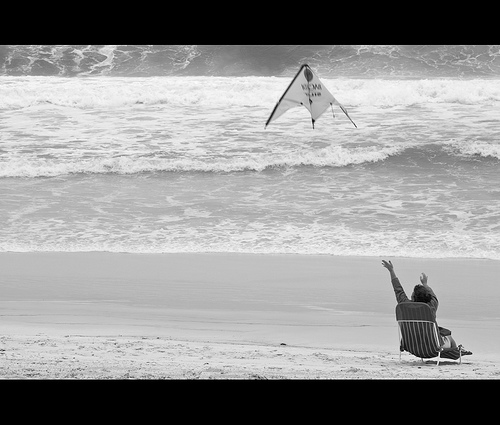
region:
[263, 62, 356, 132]
white triangular kite with a logo on it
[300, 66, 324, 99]
bacardi rum logo in black and white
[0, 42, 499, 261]
wavy ocean filled with rough and choppy salt water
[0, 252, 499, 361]
wet sandy part of the beach that's affected by the tides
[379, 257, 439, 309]
person's hands in proclamation of joy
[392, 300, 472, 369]
striped lawn or beach chair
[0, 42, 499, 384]
black and white wide photo of a kite and person sitting in a lawn chair on the beach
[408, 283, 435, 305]
person's ambiguously unidentified head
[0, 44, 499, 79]
beginning of a rather large wave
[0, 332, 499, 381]
rocky grassy sandy area for chilling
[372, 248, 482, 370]
person sitting on a chair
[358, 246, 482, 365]
a chair on the beach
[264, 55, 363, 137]
kite in the middle of sky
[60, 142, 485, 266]
a clash of ocean water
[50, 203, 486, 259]
shore of a beach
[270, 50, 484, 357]
person flying a kite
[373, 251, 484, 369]
person sitting on a chair on a beach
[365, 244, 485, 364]
person waving hands in the air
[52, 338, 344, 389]
a sand on a beach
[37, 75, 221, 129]
a body of water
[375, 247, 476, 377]
person sitting near shore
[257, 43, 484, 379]
person watching a kite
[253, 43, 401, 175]
a kite in the sky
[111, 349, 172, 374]
footprints in the sand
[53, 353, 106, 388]
footprints in the sand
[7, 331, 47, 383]
footprints in the sand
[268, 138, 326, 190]
waves crashing on shore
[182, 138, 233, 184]
waves crashing on shore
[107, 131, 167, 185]
waves crashing on shore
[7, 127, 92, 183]
waves crashing on shore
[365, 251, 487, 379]
a person on the beach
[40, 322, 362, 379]
the beach and shoreline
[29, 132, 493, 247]
waves coming in the beach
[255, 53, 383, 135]
kite in the sky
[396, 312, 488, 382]
a portable chair on beach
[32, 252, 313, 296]
wet sands on beach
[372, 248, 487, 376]
person sitting comfortably on chair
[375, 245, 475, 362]
Person sitting on the chair.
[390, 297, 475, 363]
Beach chair on the sand.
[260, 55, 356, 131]
Kite in the air.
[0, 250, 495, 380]
Sand on the beach.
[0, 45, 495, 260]
Water in the background.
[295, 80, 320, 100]
Letters on the kite.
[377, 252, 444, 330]
Person wearing long sleeves.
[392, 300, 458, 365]
Stripes on the chair.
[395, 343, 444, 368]
Metal leg on the chair.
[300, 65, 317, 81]
Dark circle on the kite.